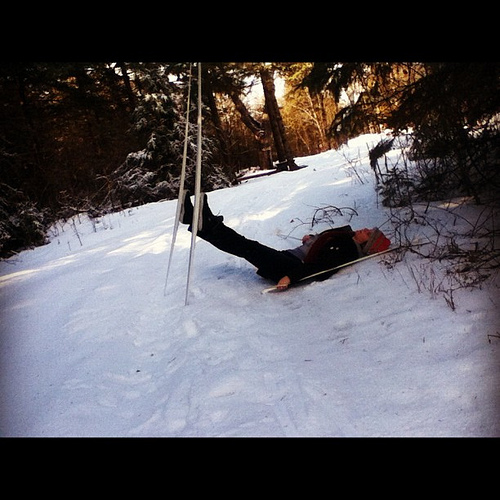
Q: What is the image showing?
A: It is showing a forest.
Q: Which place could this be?
A: It is a forest.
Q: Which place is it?
A: It is a forest.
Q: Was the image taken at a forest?
A: Yes, it was taken in a forest.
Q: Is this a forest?
A: Yes, it is a forest.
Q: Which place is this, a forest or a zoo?
A: It is a forest.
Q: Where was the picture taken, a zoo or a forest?
A: It was taken at a forest.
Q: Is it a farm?
A: No, it is a forest.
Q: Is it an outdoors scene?
A: Yes, it is outdoors.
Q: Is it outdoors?
A: Yes, it is outdoors.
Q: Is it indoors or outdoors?
A: It is outdoors.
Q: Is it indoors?
A: No, it is outdoors.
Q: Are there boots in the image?
A: Yes, there are boots.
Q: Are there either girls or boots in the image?
A: Yes, there are boots.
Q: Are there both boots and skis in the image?
A: Yes, there are both boots and skis.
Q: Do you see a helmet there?
A: No, there are no helmets.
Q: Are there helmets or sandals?
A: No, there are no helmets or sandals.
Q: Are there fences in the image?
A: No, there are no fences.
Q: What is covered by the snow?
A: The ground is covered by the snow.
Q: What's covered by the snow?
A: The ground is covered by the snow.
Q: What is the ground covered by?
A: The ground is covered by the snow.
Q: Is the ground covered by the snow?
A: Yes, the ground is covered by the snow.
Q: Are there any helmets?
A: No, there are no helmets.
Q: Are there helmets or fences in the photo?
A: No, there are no helmets or fences.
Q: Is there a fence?
A: No, there are no fences.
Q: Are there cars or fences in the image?
A: No, there are no fences or cars.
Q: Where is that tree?
A: The tree is in the forest.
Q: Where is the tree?
A: The tree is in the forest.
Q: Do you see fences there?
A: No, there are no fences.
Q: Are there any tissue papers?
A: No, there are no tissue papers.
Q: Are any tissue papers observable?
A: No, there are no tissue papers.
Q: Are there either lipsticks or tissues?
A: No, there are no tissues or lipsticks.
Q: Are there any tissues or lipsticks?
A: No, there are no tissues or lipsticks.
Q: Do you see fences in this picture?
A: No, there are no fences.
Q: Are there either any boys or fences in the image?
A: No, there are no fences or boys.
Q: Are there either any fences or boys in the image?
A: No, there are no fences or boys.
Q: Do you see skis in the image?
A: Yes, there are skis.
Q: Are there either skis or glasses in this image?
A: Yes, there are skis.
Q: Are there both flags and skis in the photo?
A: No, there are skis but no flags.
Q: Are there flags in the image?
A: No, there are no flags.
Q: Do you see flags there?
A: No, there are no flags.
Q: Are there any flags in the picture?
A: No, there are no flags.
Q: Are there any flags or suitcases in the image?
A: No, there are no flags or suitcases.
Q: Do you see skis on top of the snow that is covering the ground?
A: Yes, there are skis on top of the snow.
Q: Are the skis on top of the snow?
A: Yes, the skis are on top of the snow.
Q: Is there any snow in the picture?
A: Yes, there is snow.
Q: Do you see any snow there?
A: Yes, there is snow.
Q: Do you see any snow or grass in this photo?
A: Yes, there is snow.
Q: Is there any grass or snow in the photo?
A: Yes, there is snow.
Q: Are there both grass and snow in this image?
A: No, there is snow but no grass.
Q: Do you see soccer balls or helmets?
A: No, there are no helmets or soccer balls.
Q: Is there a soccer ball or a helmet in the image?
A: No, there are no helmets or soccer balls.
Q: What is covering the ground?
A: The snow is covering the ground.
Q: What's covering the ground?
A: The snow is covering the ground.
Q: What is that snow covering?
A: The snow is covering the ground.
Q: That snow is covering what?
A: The snow is covering the ground.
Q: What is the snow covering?
A: The snow is covering the ground.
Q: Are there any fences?
A: No, there are no fences.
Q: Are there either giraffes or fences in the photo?
A: No, there are no fences or giraffes.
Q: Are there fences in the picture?
A: No, there are no fences.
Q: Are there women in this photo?
A: Yes, there is a woman.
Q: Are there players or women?
A: Yes, there is a woman.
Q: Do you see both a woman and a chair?
A: No, there is a woman but no chairs.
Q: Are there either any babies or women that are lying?
A: Yes, the woman is lying.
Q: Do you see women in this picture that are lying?
A: Yes, there is a woman that is lying.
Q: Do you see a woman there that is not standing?
A: Yes, there is a woman that is lying .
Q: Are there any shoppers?
A: No, there are no shoppers.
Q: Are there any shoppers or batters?
A: No, there are no shoppers or batters.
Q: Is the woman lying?
A: Yes, the woman is lying.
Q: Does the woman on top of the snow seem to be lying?
A: Yes, the woman is lying.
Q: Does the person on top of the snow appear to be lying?
A: Yes, the woman is lying.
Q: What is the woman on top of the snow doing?
A: The woman is lying.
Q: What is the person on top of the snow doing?
A: The woman is lying.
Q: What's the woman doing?
A: The woman is lying.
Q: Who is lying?
A: The woman is lying.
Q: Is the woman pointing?
A: No, the woman is lying.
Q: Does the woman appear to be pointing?
A: No, the woman is lying.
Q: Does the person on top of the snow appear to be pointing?
A: No, the woman is lying.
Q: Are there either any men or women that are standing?
A: No, there is a woman but she is lying.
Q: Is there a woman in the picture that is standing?
A: No, there is a woman but she is lying.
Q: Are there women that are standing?
A: No, there is a woman but she is lying.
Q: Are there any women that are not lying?
A: No, there is a woman but she is lying.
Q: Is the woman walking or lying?
A: The woman is lying.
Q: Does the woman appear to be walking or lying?
A: The woman is lying.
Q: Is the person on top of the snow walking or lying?
A: The woman is lying.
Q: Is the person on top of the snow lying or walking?
A: The woman is lying.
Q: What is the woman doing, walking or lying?
A: The woman is lying.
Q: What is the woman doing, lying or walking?
A: The woman is lying.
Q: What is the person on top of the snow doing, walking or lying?
A: The woman is lying.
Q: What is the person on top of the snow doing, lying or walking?
A: The woman is lying.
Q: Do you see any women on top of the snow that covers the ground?
A: Yes, there is a woman on top of the snow.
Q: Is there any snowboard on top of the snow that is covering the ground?
A: No, there is a woman on top of the snow.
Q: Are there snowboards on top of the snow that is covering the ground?
A: No, there is a woman on top of the snow.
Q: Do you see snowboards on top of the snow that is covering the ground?
A: No, there is a woman on top of the snow.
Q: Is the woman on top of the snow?
A: Yes, the woman is on top of the snow.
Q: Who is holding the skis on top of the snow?
A: The woman is holding the skis.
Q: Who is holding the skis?
A: The woman is holding the skis.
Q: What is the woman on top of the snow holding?
A: The woman is holding the skis.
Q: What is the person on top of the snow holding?
A: The woman is holding the skis.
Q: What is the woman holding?
A: The woman is holding the skis.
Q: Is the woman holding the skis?
A: Yes, the woman is holding the skis.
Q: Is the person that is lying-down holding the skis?
A: Yes, the woman is holding the skis.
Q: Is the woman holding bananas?
A: No, the woman is holding the skis.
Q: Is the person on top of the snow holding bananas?
A: No, the woman is holding the skis.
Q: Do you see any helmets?
A: No, there are no helmets.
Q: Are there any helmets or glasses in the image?
A: No, there are no helmets or glasses.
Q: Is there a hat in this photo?
A: Yes, there is a hat.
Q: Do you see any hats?
A: Yes, there is a hat.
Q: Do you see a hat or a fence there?
A: Yes, there is a hat.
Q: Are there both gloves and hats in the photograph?
A: No, there is a hat but no gloves.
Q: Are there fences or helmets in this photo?
A: No, there are no fences or helmets.